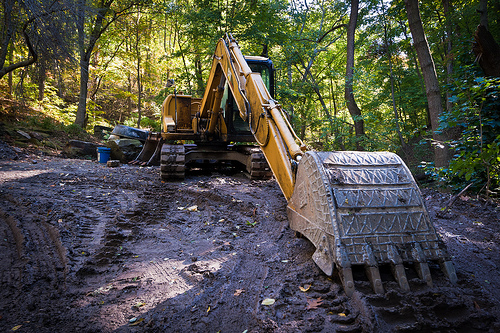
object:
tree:
[406, 0, 450, 189]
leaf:
[459, 194, 470, 201]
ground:
[255, 311, 311, 331]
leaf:
[234, 288, 246, 297]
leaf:
[299, 284, 312, 292]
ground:
[432, 300, 495, 332]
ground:
[0, 221, 80, 333]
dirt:
[5, 189, 136, 329]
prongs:
[336, 260, 356, 297]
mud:
[359, 288, 500, 333]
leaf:
[261, 298, 276, 306]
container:
[96, 147, 111, 163]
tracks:
[63, 198, 115, 275]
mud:
[167, 144, 176, 177]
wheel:
[241, 145, 273, 180]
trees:
[4, 0, 49, 77]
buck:
[96, 147, 111, 164]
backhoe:
[159, 32, 457, 297]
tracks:
[160, 143, 185, 181]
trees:
[97, 24, 145, 99]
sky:
[339, 8, 401, 29]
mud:
[48, 177, 124, 284]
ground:
[189, 178, 244, 241]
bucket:
[286, 151, 458, 298]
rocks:
[60, 140, 106, 159]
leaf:
[306, 296, 324, 310]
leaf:
[219, 219, 225, 223]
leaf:
[205, 306, 211, 316]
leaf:
[186, 205, 200, 214]